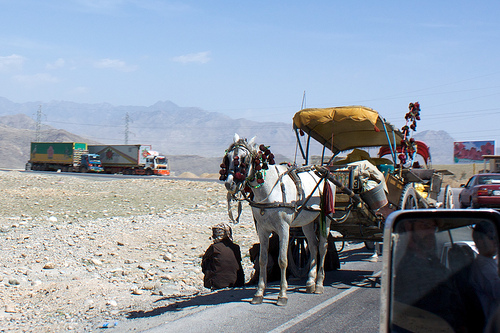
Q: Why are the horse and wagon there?
A: To transport things.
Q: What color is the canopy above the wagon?
A: Dark yellow.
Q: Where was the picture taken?
A: On a road.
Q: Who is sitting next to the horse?
A: A man in brown outfit.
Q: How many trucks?
A: Two.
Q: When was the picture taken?
A: During daytime.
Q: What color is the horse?
A: White.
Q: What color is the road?
A: Grey.